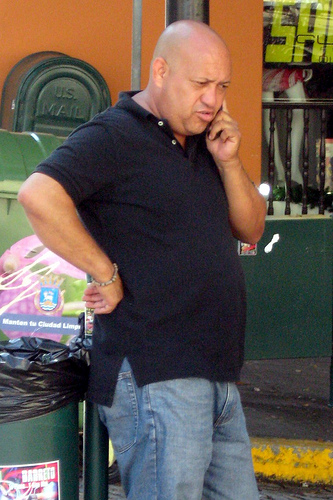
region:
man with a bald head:
[143, 16, 228, 127]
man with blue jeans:
[89, 346, 268, 492]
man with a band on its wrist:
[88, 257, 126, 294]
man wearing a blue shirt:
[57, 90, 261, 411]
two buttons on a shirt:
[151, 118, 182, 157]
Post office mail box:
[11, 39, 114, 140]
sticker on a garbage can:
[0, 458, 65, 498]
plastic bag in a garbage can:
[2, 333, 90, 408]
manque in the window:
[256, 44, 312, 188]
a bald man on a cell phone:
[116, 3, 303, 164]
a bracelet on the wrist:
[84, 252, 147, 325]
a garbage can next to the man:
[19, 340, 73, 498]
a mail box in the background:
[2, 33, 115, 139]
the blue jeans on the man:
[95, 345, 295, 492]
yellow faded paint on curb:
[244, 421, 324, 485]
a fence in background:
[259, 88, 331, 169]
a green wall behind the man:
[267, 257, 330, 333]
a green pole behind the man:
[74, 353, 108, 498]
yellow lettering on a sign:
[265, 12, 331, 66]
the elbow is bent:
[12, 169, 77, 224]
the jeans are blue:
[87, 338, 258, 494]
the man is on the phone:
[44, 19, 267, 490]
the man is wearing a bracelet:
[86, 275, 122, 287]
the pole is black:
[84, 431, 107, 494]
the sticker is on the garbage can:
[7, 460, 62, 498]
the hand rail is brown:
[264, 94, 331, 211]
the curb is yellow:
[264, 435, 328, 482]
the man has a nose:
[201, 91, 218, 108]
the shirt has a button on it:
[169, 140, 179, 146]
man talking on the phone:
[40, 16, 268, 373]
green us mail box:
[3, 46, 108, 111]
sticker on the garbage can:
[0, 457, 61, 498]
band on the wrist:
[84, 262, 125, 286]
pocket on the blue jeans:
[104, 367, 141, 458]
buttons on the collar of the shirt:
[155, 119, 176, 151]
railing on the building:
[258, 100, 330, 222]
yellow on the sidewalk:
[250, 432, 331, 487]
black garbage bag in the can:
[2, 357, 58, 407]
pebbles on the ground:
[253, 380, 272, 398]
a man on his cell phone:
[20, 21, 266, 499]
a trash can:
[0, 338, 82, 498]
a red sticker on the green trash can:
[1, 462, 58, 499]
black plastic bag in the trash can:
[0, 339, 88, 420]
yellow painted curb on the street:
[247, 439, 330, 481]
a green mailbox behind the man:
[4, 51, 110, 134]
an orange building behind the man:
[1, 0, 260, 187]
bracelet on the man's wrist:
[91, 262, 118, 286]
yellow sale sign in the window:
[263, 2, 331, 64]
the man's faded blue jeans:
[97, 356, 259, 498]